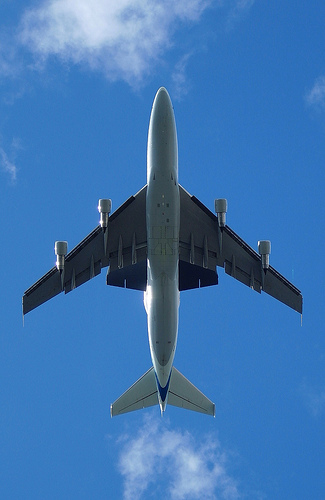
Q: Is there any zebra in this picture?
A: No, there are no zebras.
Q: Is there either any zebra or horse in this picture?
A: No, there are no zebras or horses.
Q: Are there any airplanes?
A: Yes, there is an airplane.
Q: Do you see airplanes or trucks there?
A: Yes, there is an airplane.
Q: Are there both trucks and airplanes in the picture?
A: No, there is an airplane but no trucks.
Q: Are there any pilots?
A: No, there are no pilots.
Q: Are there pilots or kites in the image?
A: No, there are no pilots or kites.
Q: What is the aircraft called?
A: The aircraft is an airplane.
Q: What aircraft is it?
A: The aircraft is an airplane.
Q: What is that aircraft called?
A: This is an airplane.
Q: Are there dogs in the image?
A: No, there are no dogs.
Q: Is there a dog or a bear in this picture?
A: No, there are no dogs or bears.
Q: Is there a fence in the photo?
A: No, there are no fences.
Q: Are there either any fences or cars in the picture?
A: No, there are no fences or cars.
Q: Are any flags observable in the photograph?
A: No, there are no flags.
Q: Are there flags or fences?
A: No, there are no flags or fences.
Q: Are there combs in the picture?
A: No, there are no combs.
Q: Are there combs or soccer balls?
A: No, there are no combs or soccer balls.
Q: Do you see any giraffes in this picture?
A: No, there are no giraffes.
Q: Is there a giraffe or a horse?
A: No, there are no giraffes or horses.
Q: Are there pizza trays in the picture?
A: No, there are no pizza trays.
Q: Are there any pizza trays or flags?
A: No, there are no pizza trays or flags.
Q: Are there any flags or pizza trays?
A: No, there are no pizza trays or flags.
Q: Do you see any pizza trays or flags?
A: No, there are no pizza trays or flags.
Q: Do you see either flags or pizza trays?
A: No, there are no pizza trays or flags.